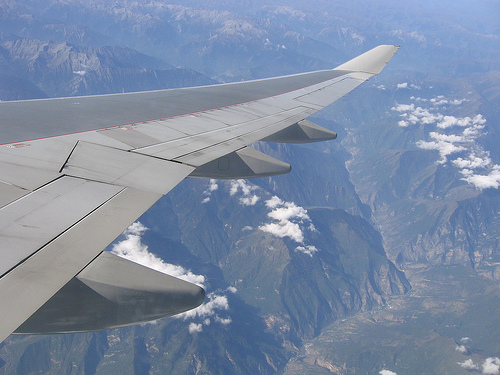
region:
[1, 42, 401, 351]
wings of a gray colored jet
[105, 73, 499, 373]
white colored fluffy clouds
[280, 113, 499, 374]
barren valley with a creek running through it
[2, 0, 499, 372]
gray colored mountainous landscape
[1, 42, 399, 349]
gray metal wings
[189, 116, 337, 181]
two engines on the gray wing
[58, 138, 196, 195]
grooves in the metal of the jet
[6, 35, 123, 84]
jagged mountain top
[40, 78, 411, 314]
the plane is in the sky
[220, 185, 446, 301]
clouds over the mountain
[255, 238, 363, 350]
hills in the mountain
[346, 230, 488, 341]
valley in the mountain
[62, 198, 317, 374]
propellers on the wing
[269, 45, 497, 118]
the wing is slanted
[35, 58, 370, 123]
the wing is gray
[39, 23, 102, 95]
sun shines on the mountain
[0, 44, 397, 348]
A large, gray jet wing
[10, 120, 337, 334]
Three spare fuel tanks in a row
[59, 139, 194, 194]
A metal spoiler on a jet wing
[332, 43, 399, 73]
The winglet of a modern jet wing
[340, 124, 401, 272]
A small chasm in the mountains where a river flows through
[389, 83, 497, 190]
A small cloud formation several thousand feet below the jet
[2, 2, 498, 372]
A large mountain chain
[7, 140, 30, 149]
A guide light on a jet's wing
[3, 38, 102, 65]
The peak of a mountain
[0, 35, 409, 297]
long tip to wing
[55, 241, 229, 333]
white bottom bf wing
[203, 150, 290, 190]
white bottom piece of wing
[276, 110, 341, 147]
white bottom piece of wing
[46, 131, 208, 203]
flap on side of wing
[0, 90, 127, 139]
grey front of wing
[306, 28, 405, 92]
curved tip of wing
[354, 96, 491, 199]
clouds in the sky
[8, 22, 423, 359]
a wing on an airplane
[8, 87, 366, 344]
three engines on a plane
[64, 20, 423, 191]
the wing is silver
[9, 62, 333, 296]
this wing is long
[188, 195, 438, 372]
the plane is flying over mountains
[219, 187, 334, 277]
snow on the mountain top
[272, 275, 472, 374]
a valley beneath the mountains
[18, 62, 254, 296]
the wing has many different sections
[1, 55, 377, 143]
this part of the wing curves upward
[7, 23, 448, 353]
this plane is flying high over the mountains